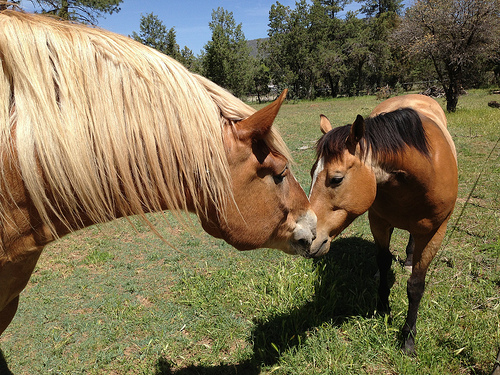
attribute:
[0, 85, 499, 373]
grass — green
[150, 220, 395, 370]
shadow — horse's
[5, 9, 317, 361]
horses — on the scene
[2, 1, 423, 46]
sky — clear, blue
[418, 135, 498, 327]
shadow — fence's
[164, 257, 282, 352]
grass — dead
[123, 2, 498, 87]
trees — in the background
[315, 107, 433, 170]
hair — black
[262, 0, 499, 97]
trees — in the distance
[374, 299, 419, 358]
hooves — dark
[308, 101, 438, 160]
hair — dark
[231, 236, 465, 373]
shadow — horse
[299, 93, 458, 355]
horse — kissing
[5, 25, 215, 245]
hair — blonde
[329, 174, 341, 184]
eye — dark